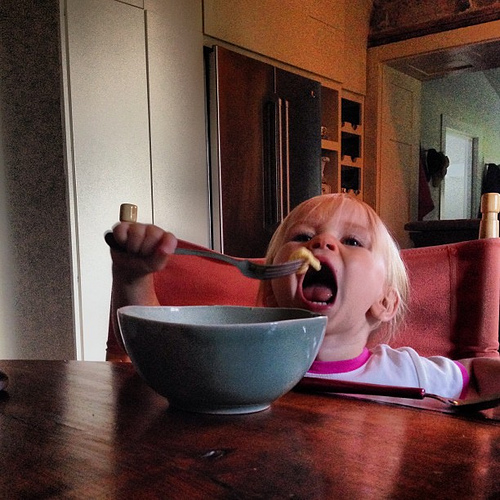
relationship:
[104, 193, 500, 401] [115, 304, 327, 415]
boy eating from a bowl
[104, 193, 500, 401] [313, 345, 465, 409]
boy wearing shirt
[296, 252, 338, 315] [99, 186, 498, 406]
mouth on kid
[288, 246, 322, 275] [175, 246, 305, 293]
food on fork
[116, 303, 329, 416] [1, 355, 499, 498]
bowl on table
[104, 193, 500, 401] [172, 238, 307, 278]
boy with fork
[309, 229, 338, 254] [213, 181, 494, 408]
nose on child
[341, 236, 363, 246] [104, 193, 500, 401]
eye on boy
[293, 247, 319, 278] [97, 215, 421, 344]
food on fork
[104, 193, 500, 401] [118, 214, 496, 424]
boy sitting on chair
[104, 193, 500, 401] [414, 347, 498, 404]
boy has arm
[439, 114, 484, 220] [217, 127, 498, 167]
doorway on background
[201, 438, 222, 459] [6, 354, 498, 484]
knot on table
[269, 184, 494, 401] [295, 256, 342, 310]
boy has mouth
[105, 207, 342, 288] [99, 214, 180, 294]
fork on hand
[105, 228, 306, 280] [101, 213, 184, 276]
fork on hand